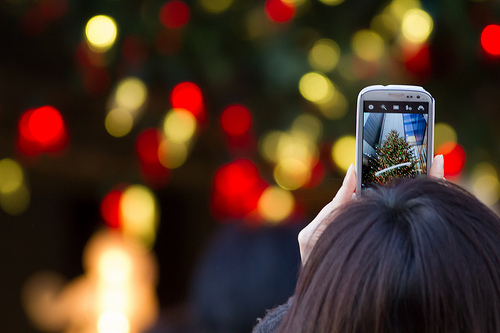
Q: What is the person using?
A: A smartphone.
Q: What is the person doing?
A: Taking a picture.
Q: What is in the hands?
A: A phone.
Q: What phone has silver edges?
A: The phone.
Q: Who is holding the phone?
A: The person.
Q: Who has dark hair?
A: The woman.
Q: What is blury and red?
A: The tree lights.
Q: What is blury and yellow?
A: The tree lights.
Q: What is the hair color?
A: Brown.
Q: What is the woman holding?
A: Phone.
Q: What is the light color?
A: Red.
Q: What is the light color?
A: Red.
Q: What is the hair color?
A: Dark.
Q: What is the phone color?
A: White.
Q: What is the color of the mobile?
A: Grey.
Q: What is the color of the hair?
A: Black.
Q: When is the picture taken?
A: Night time.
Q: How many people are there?
A: 1.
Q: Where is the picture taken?
A: At a Christmas tree.